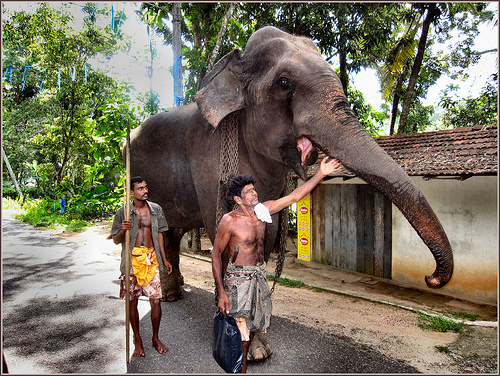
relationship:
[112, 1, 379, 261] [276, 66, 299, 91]
elephant has eye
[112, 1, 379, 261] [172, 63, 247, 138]
elephant has ear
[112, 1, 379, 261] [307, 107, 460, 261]
elephant has trunk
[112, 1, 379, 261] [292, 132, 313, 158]
elephant has tongue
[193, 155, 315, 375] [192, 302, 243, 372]
man has bag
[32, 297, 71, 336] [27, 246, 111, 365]
shadow on ground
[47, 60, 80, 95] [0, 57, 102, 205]
leave on tree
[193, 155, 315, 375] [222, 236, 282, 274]
man has wasit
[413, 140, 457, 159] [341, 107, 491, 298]
roof of building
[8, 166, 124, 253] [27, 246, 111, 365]
weed on ground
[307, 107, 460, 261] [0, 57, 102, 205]
trunk of tree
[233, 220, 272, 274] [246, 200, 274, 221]
chest visible under shirt